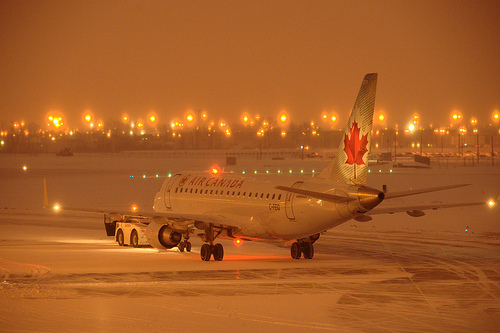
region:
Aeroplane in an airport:
[147, 73, 381, 268]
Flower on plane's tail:
[340, 115, 370, 178]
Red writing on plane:
[184, 171, 244, 190]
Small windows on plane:
[173, 185, 283, 205]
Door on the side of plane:
[163, 170, 185, 210]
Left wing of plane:
[66, 200, 223, 227]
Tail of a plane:
[323, 68, 378, 183]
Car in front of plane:
[104, 210, 151, 247]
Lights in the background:
[0, 105, 499, 155]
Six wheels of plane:
[176, 233, 320, 264]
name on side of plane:
[175, 175, 257, 193]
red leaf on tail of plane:
[334, 118, 384, 188]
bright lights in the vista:
[91, 95, 252, 134]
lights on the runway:
[255, 157, 394, 179]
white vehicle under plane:
[101, 214, 179, 254]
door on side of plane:
[279, 170, 307, 240]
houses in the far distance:
[109, 115, 253, 154]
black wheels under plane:
[190, 237, 233, 259]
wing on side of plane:
[142, 219, 189, 250]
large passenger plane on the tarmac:
[125, 90, 458, 267]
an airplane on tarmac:
[41, 73, 495, 264]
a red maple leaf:
[338, 121, 368, 182]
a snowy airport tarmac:
[0, 154, 499, 331]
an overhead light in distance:
[83, 113, 92, 124]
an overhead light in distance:
[94, 120, 104, 130]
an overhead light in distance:
[88, 120, 95, 130]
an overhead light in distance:
[119, 112, 127, 124]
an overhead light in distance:
[129, 120, 135, 128]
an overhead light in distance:
[136, 117, 143, 129]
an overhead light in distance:
[145, 110, 156, 125]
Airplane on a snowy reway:
[130, 119, 424, 278]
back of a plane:
[368, 190, 375, 202]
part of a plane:
[279, 204, 285, 221]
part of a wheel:
[201, 245, 206, 250]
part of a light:
[281, 106, 295, 137]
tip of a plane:
[372, 184, 380, 206]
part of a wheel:
[209, 230, 224, 251]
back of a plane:
[343, 210, 348, 220]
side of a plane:
[242, 191, 254, 206]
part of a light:
[412, 90, 439, 141]